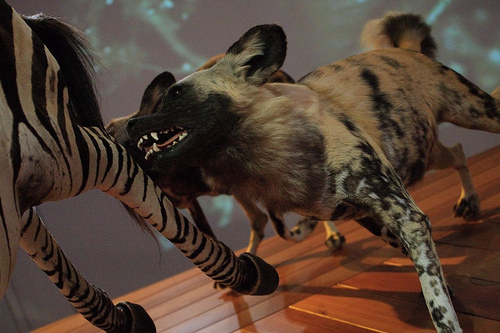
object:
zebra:
[8, 18, 139, 247]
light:
[92, 6, 485, 299]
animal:
[55, 21, 106, 122]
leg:
[90, 141, 193, 245]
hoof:
[233, 228, 294, 308]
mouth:
[109, 13, 297, 237]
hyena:
[202, 38, 422, 218]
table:
[316, 259, 389, 332]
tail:
[379, 13, 430, 44]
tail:
[63, 35, 116, 103]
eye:
[171, 82, 201, 100]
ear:
[247, 24, 304, 78]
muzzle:
[128, 49, 167, 99]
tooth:
[144, 120, 183, 148]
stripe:
[27, 59, 79, 134]